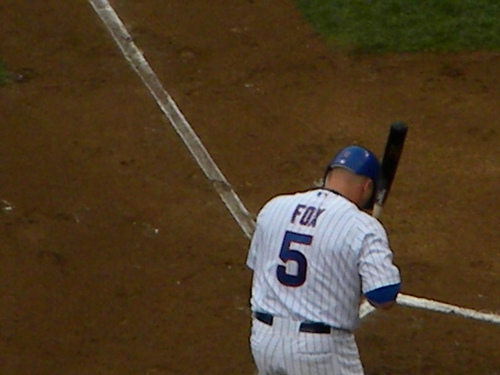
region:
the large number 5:
[274, 226, 319, 295]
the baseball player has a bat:
[240, 141, 402, 373]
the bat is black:
[360, 110, 411, 220]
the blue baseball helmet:
[329, 147, 377, 177]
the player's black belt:
[252, 303, 343, 342]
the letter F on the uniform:
[285, 200, 303, 223]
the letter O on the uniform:
[298, 203, 313, 227]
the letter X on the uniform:
[307, 205, 323, 228]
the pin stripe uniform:
[248, 175, 398, 369]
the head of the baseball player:
[320, 135, 387, 209]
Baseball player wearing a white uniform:
[243, 120, 410, 372]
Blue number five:
[273, 228, 313, 290]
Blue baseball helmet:
[325, 143, 382, 185]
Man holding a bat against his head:
[242, 116, 409, 373]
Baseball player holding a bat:
[240, 119, 410, 374]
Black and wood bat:
[367, 119, 409, 224]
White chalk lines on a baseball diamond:
[87, 1, 498, 333]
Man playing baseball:
[241, 118, 409, 373]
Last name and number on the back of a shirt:
[272, 200, 327, 288]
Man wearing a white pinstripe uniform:
[242, 118, 417, 374]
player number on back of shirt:
[267, 228, 323, 298]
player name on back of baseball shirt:
[288, 201, 335, 228]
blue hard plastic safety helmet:
[305, 135, 383, 208]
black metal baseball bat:
[373, 103, 420, 222]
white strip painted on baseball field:
[129, 38, 236, 228]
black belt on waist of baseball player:
[247, 308, 337, 343]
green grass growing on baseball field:
[328, 0, 498, 52]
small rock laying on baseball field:
[0, 198, 26, 219]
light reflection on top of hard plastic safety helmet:
[338, 137, 374, 175]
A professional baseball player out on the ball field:
[238, 110, 421, 372]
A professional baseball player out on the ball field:
[236, 114, 416, 371]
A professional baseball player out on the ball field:
[237, 115, 420, 371]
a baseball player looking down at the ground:
[244, 115, 413, 374]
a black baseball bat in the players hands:
[372, 116, 410, 216]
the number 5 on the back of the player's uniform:
[273, 228, 313, 291]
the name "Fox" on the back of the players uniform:
[291, 200, 324, 230]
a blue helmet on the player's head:
[317, 141, 384, 184]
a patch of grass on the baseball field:
[296, 0, 498, 53]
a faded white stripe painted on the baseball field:
[90, 0, 259, 236]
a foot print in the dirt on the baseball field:
[7, 58, 42, 88]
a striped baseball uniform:
[241, 188, 402, 373]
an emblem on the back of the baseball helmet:
[341, 150, 352, 159]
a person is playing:
[200, 121, 397, 359]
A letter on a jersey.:
[294, 200, 306, 224]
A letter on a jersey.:
[301, 205, 315, 224]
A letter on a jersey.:
[311, 205, 331, 230]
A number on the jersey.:
[271, 227, 316, 271]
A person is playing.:
[221, 131, 402, 363]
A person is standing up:
[234, 147, 389, 373]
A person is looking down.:
[230, 155, 380, 368]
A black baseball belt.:
[247, 308, 273, 328]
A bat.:
[363, 105, 405, 222]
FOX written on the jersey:
[293, 197, 329, 229]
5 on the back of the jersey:
[272, 226, 317, 291]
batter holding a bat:
[323, 116, 411, 309]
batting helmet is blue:
[326, 136, 380, 182]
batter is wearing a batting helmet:
[317, 134, 384, 201]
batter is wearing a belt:
[247, 298, 358, 345]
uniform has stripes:
[243, 181, 401, 372]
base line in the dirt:
[84, 2, 269, 247]